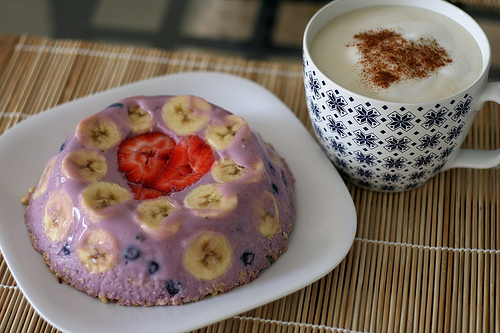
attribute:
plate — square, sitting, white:
[2, 71, 360, 332]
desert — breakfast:
[23, 94, 300, 303]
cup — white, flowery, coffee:
[302, 0, 499, 193]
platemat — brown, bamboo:
[367, 198, 499, 332]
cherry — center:
[118, 129, 216, 200]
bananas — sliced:
[62, 113, 131, 212]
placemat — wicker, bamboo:
[362, 191, 500, 330]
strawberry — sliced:
[118, 131, 215, 207]